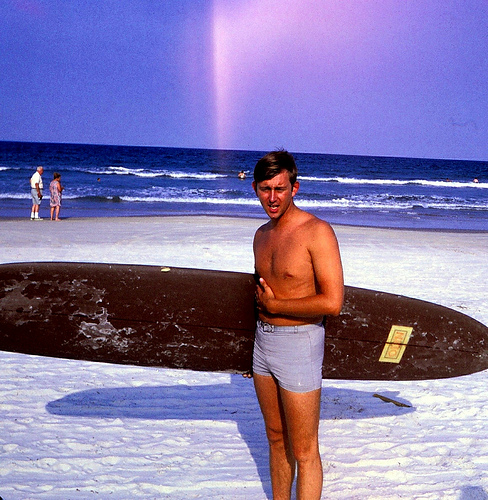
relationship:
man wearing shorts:
[252, 147, 345, 500] [248, 320, 324, 386]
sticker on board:
[372, 311, 408, 372] [4, 263, 487, 381]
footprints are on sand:
[362, 414, 444, 479] [0, 219, 488, 498]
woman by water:
[44, 167, 71, 222] [0, 140, 482, 222]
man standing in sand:
[252, 147, 345, 500] [0, 219, 488, 498]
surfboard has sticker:
[0, 261, 487, 381] [376, 324, 412, 365]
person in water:
[238, 170, 247, 178] [0, 139, 487, 230]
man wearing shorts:
[253, 147, 341, 498] [252, 320, 325, 394]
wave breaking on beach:
[0, 188, 486, 208] [2, 179, 482, 498]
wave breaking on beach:
[342, 192, 475, 201] [2, 179, 482, 498]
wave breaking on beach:
[0, 165, 488, 210] [2, 179, 482, 498]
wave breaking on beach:
[2, 164, 228, 180] [2, 179, 482, 498]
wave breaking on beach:
[296, 172, 487, 188] [2, 179, 482, 498]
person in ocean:
[237, 168, 253, 178] [0, 140, 485, 226]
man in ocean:
[252, 147, 345, 500] [2, 136, 487, 231]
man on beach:
[252, 147, 345, 500] [2, 179, 482, 498]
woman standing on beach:
[49, 172, 64, 221] [2, 142, 487, 499]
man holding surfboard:
[252, 147, 345, 500] [4, 252, 486, 394]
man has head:
[252, 147, 345, 500] [237, 139, 311, 231]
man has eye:
[252, 147, 345, 500] [255, 182, 272, 195]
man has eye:
[252, 147, 345, 500] [256, 186, 271, 193]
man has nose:
[252, 147, 345, 500] [264, 194, 279, 201]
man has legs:
[252, 147, 345, 500] [250, 372, 344, 493]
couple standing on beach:
[29, 165, 61, 219] [2, 179, 482, 498]